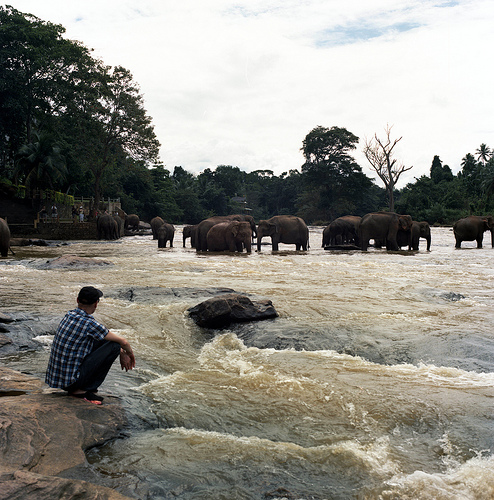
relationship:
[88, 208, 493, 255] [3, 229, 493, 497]
elephants in water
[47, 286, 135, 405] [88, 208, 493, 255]
man watching elephants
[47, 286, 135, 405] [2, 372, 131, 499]
man on a rock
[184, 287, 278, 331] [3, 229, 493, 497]
rock in water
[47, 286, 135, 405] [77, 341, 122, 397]
man wearing black pants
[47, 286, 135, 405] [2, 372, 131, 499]
man on a large rock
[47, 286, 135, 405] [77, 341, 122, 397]
man wears dark blue jeans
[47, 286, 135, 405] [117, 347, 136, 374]
man crosses hands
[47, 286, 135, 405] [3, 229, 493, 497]
man sits by water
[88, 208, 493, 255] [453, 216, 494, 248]
elephants are in a elephants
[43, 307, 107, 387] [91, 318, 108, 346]
shirt has short sleeves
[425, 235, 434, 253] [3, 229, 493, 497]
trunk in water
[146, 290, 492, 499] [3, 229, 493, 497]
rapids on water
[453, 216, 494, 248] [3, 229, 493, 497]
elephants in water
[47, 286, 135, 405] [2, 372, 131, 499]
man crouching on a rock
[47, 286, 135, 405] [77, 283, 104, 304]
man wears a cap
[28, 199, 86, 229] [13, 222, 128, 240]
people on a ledge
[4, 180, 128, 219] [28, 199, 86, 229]
fence behind people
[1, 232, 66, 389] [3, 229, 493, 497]
rocks in water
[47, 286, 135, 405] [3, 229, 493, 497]
man by water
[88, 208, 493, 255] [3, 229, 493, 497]
elephants stand in water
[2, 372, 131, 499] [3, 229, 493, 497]
rock by water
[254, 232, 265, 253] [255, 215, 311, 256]
trunk of an elephant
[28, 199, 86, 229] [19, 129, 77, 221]
people stand near tree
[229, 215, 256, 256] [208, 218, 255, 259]
head of an elephant